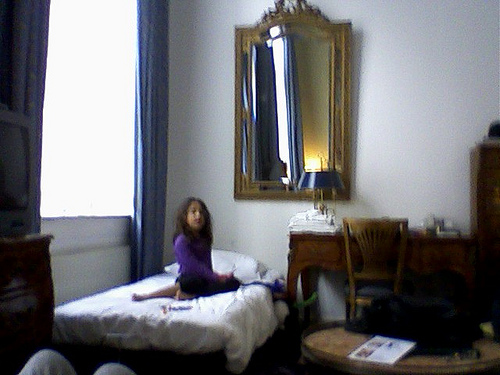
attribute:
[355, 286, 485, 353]
backpack — sitting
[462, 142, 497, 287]
dresser — wooden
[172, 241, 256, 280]
pillow — white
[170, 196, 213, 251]
hair — dark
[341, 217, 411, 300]
desk chair — wooden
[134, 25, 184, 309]
curtains — blue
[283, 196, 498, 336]
desk — antique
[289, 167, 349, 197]
lampshade — blue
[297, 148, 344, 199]
lamb — bedside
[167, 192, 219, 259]
hair — dark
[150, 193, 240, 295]
girl — wearing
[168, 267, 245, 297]
pants — black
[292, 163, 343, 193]
shade — blue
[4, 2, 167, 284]
curtains — blue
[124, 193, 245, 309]
girl — sitted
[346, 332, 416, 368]
material — reading, sitting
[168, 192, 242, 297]
girl — little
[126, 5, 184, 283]
drapes — blue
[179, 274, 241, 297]
pants — dark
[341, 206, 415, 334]
chair — wooden